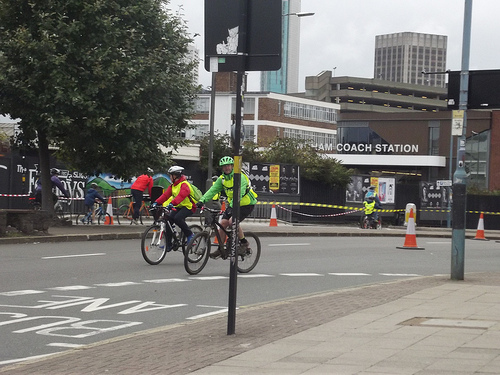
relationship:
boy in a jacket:
[146, 166, 203, 251] [145, 177, 195, 209]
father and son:
[360, 182, 383, 232] [360, 195, 380, 220]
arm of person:
[169, 181, 191, 205] [153, 163, 202, 246]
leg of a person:
[129, 187, 142, 218] [129, 166, 158, 216]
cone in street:
[396, 209, 425, 253] [2, 235, 139, 360]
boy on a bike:
[156, 162, 206, 247] [139, 205, 204, 263]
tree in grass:
[51, 37, 181, 166] [0, 214, 99, 234]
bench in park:
[1, 193, 61, 225] [5, 4, 183, 227]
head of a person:
[217, 155, 236, 175] [186, 152, 258, 257]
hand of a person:
[165, 199, 183, 220] [143, 160, 200, 242]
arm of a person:
[169, 183, 189, 206] [192, 150, 264, 253]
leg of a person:
[206, 202, 233, 259] [196, 155, 259, 257]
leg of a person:
[213, 202, 249, 255] [206, 153, 258, 241]